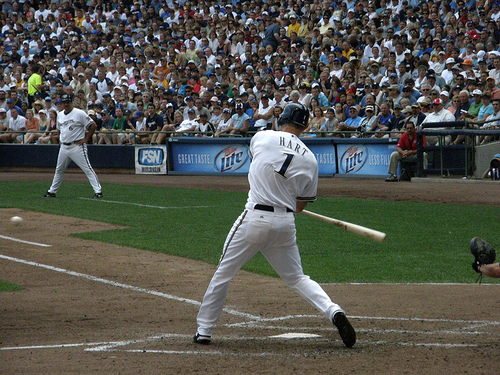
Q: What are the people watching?
A: Baseball game.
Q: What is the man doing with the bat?
A: Preparing to hit the ball.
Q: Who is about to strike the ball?
A: Player named Hart.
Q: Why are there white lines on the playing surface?
A: To indicate boundaries.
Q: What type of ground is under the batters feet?
A: Dirt.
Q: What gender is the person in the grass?
A: Male.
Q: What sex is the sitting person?
A: Male.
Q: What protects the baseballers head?
A: Helmet.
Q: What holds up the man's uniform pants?
A: Belt.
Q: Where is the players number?
A: On his back.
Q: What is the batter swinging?
A: A bat.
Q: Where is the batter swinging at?
A: In the batters box.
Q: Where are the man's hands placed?
A: On his hips.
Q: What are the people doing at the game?
A: Spectating.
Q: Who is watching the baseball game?
A: Spectators.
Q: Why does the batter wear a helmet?
A: To protect head.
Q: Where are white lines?
A: On the dirt.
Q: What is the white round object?
A: A baseball.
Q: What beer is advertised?
A: Miller Lite.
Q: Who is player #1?
A: Hart.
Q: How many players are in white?
A: Two.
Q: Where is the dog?
A: There is no dog.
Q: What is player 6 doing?
A: Standing.